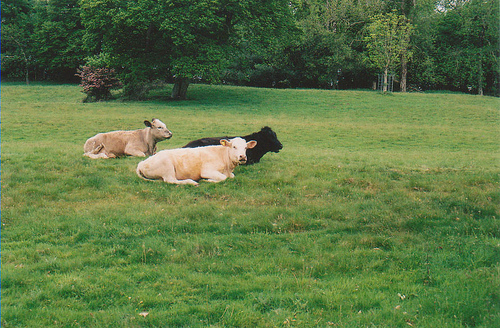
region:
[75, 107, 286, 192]
three cows lying on green grass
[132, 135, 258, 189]
a white cow near a black cow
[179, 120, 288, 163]
black cow facing right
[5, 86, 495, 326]
field is cover with green grass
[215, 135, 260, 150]
two big ears of cow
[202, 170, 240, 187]
front legs of cow are fold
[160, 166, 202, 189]
back leg is extended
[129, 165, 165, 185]
tail of cow is long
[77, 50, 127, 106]
a small tree next a big tree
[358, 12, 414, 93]
a small tree is protected with a fence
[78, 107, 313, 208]
the cows are lying down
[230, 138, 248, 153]
the cow has eyes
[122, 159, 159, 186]
the cow has a tail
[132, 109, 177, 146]
the cow has a head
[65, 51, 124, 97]
the leaves are purple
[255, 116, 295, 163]
the cow has a black head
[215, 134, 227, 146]
the tag is yellow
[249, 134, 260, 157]
the cow has an ear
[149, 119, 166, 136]
the cow has an eye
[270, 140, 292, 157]
the cows mouth is open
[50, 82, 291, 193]
Three cows sitting on grass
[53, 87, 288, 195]
Three cows sitting during the day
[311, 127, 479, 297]
Lots of green grass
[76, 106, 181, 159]
One tan cow sitting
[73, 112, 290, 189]
One cow is black and two are not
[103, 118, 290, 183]
Two cows are tan and one is not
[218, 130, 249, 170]
Cow is looking at camera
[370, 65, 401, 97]
Trunk of tree is protected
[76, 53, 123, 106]
Bush has pink flowers on it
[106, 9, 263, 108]
Not many shadows today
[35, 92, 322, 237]
3 cows on the grass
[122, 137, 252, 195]
the cow is white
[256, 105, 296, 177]
the cow is black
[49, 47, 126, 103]
bushes under the tree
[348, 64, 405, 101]
tree has fence around it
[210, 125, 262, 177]
cow is looking at the camera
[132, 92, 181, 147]
cow is looking to the right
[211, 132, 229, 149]
the ear is tagged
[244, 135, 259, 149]
the ear is pink inside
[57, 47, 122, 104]
the leaves are purplish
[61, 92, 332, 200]
three cows in a field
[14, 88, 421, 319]
the field of grass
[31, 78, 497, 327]
the grass is green and low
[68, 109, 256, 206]
tow cream colored cows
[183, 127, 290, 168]
the black cow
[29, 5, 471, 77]
the trees with green leaves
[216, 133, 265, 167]
the head of the cow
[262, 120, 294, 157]
the head of the cow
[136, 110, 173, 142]
the head of the cow